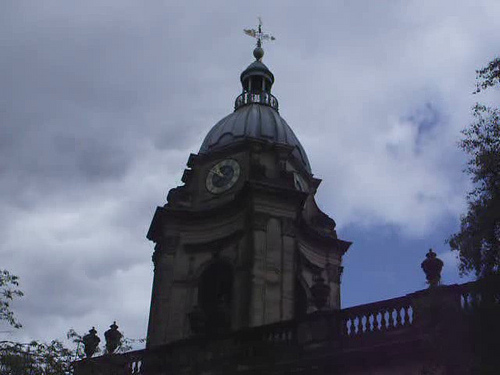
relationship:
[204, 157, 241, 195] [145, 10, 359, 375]
clock on side of a building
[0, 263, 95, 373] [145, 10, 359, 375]
tree near a building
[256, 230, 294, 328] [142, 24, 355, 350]
stone work in church steeple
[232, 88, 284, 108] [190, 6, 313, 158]
stand on dome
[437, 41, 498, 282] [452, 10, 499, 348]
tree on side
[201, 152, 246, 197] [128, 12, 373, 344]
clock on building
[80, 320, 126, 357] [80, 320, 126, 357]
two decorations style two decorations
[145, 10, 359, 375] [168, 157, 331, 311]
building has design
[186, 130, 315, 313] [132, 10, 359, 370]
designs on building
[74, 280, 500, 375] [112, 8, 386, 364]
cement railing front building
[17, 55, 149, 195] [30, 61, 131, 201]
clouds has mysterious shapes